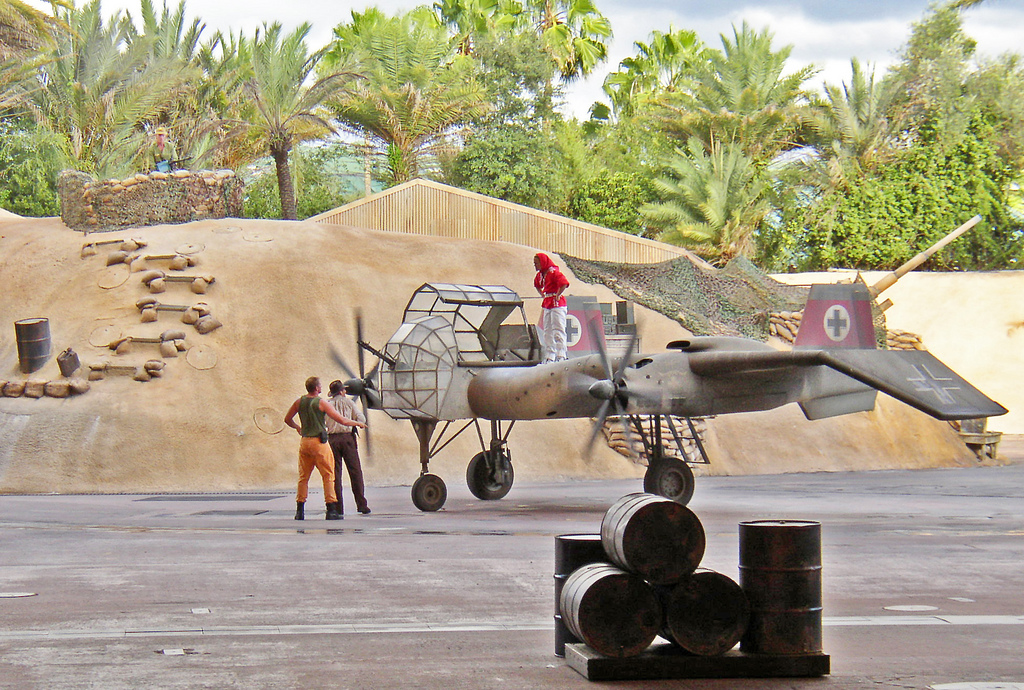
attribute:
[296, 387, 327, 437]
shirt — green, sleeveless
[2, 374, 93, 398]
step — stone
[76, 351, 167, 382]
step — stone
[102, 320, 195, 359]
step — stone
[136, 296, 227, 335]
step — stone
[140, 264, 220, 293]
step — stone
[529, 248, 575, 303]
top — red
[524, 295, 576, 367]
pants — white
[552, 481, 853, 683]
cylinders — pile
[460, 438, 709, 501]
wheels — back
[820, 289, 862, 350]
cross — black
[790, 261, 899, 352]
stabilizer — vertical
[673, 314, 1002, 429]
stabilizers — horizontal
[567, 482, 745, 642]
barrels — metal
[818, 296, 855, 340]
decal — red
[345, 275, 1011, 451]
airplane — nazi, old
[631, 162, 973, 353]
tree — green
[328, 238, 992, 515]
airplane — vintage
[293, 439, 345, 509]
pants — orange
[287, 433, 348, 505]
pants — orange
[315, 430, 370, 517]
pants — brown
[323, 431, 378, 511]
pants — brown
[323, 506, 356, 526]
shoe — black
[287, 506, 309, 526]
shoe — black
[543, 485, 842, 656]
barrels — metal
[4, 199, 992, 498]
mound — large, brown